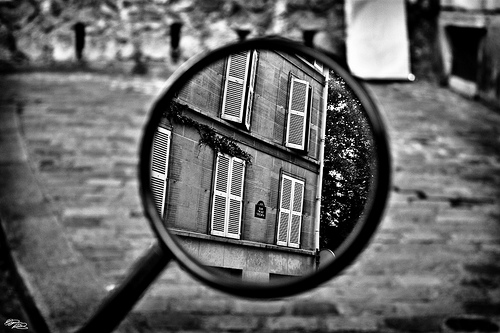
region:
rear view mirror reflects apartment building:
[69, 31, 409, 331]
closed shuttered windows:
[143, 125, 318, 251]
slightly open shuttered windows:
[213, 48, 313, 158]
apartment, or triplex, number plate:
[251, 197, 268, 222]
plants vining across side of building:
[160, 103, 256, 164]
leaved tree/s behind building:
[318, 55, 376, 251]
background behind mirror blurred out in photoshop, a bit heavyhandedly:
[1, 0, 499, 332]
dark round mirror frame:
[132, 32, 397, 305]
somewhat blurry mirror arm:
[68, 240, 174, 331]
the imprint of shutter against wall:
[161, 138, 214, 237]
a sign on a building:
[251, 195, 275, 224]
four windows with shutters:
[196, 57, 321, 270]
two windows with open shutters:
[212, 41, 322, 138]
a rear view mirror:
[127, 41, 396, 308]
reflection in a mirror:
[151, 94, 356, 266]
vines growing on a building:
[149, 101, 264, 162]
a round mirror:
[125, 44, 407, 315]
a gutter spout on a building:
[290, 72, 337, 263]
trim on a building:
[141, 104, 329, 161]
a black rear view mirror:
[124, 58, 405, 290]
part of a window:
[275, 157, 307, 207]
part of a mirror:
[286, 189, 322, 266]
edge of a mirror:
[351, 190, 394, 265]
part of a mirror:
[280, 203, 313, 251]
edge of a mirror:
[337, 253, 362, 277]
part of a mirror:
[267, 175, 302, 225]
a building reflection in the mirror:
[147, 49, 329, 268]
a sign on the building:
[251, 194, 271, 222]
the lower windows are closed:
[108, 131, 311, 248]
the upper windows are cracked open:
[221, 44, 328, 163]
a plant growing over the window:
[167, 107, 263, 166]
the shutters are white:
[155, 52, 313, 252]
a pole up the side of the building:
[301, 53, 335, 261]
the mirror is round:
[128, 32, 405, 314]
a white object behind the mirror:
[336, 2, 417, 89]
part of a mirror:
[253, 152, 293, 202]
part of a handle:
[121, 259, 168, 316]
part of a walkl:
[397, 233, 424, 278]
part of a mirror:
[287, 223, 308, 261]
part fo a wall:
[399, 220, 438, 275]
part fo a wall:
[386, 280, 408, 330]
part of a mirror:
[261, 228, 282, 260]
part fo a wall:
[379, 240, 409, 293]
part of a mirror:
[283, 170, 315, 220]